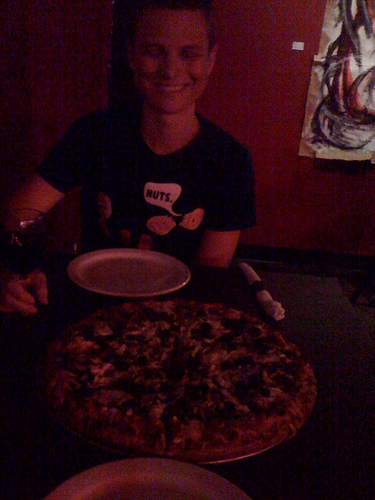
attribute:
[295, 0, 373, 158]
paper — piece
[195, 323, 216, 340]
sausage — ground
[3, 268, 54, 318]
hand — person's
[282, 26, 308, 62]
square — small, white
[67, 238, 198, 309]
plate — empty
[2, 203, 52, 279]
glass — wine glass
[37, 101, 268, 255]
tshirt — silly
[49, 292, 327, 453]
pizza — delicious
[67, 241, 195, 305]
plate — circular, white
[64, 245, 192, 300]
plate — empty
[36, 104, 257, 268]
shirt — person's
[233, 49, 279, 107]
walls — red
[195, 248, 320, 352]
napkin — rolled up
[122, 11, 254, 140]
face — happy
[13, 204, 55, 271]
wine — red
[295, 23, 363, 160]
painting — abstract